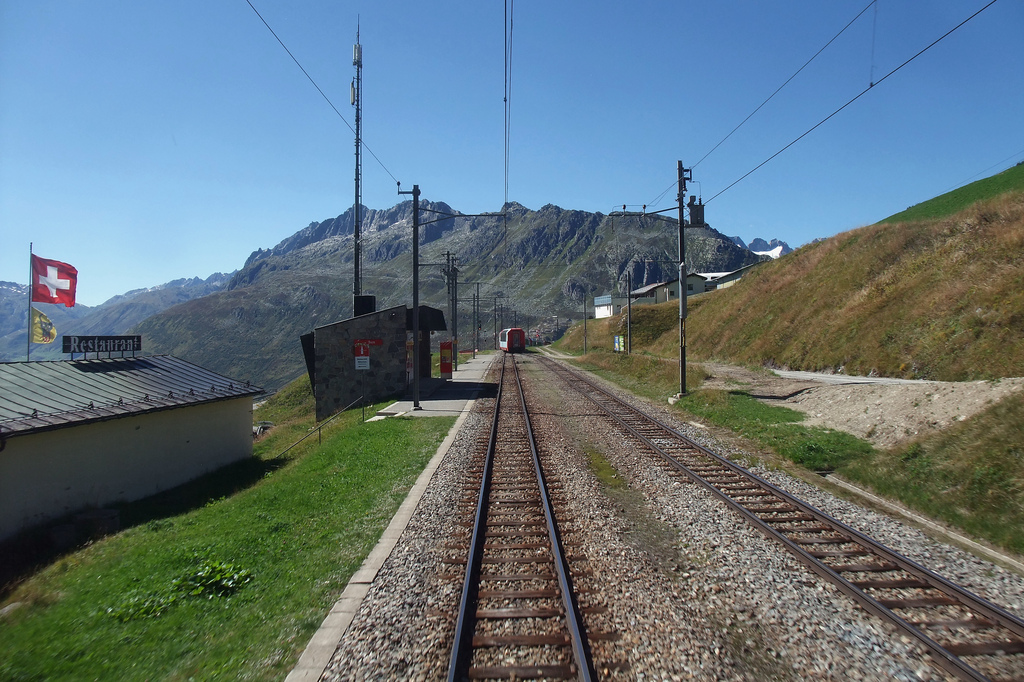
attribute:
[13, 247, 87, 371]
flag — red, white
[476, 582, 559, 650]
planks — wood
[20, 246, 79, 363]
flag — Swiss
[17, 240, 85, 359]
flag — Swiss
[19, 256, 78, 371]
flag — red, white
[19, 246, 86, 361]
flag — yellow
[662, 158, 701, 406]
pole — light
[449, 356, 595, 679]
track — railroad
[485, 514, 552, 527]
plank — wood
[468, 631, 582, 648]
plank — wood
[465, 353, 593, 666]
track — railroad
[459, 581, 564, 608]
plank — wood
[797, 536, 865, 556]
plank — wood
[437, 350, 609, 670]
track — railroad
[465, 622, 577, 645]
plank — wood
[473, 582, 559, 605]
plank — wood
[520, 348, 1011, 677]
track — railroad